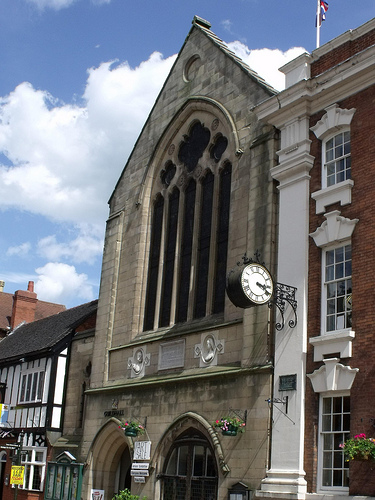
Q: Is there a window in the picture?
A: Yes, there are windows.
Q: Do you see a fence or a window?
A: Yes, there are windows.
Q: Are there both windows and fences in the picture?
A: No, there are windows but no fences.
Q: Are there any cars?
A: No, there are no cars.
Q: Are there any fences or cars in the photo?
A: No, there are no cars or fences.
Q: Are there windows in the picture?
A: Yes, there is a window.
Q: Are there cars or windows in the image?
A: Yes, there is a window.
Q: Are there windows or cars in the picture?
A: Yes, there is a window.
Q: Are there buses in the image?
A: No, there are no buses.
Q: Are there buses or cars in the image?
A: No, there are no buses or cars.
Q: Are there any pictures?
A: No, there are no pictures.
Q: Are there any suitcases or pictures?
A: No, there are no pictures or suitcases.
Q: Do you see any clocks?
A: Yes, there is a clock.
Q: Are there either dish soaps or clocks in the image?
A: Yes, there is a clock.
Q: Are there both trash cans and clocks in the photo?
A: No, there is a clock but no trash cans.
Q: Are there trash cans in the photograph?
A: No, there are no trash cans.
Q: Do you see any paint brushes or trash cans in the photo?
A: No, there are no trash cans or paint brushes.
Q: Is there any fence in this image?
A: No, there are no fences.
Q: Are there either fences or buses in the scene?
A: No, there are no fences or buses.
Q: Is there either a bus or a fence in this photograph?
A: No, there are no fences or buses.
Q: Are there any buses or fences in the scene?
A: No, there are no fences or buses.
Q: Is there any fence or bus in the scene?
A: No, there are no fences or buses.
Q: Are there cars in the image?
A: No, there are no cars.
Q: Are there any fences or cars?
A: No, there are no cars or fences.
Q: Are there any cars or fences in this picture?
A: No, there are no cars or fences.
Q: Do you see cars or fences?
A: No, there are no cars or fences.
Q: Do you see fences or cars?
A: No, there are no cars or fences.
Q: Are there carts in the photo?
A: No, there are no carts.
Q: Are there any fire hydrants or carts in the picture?
A: No, there are no carts or fire hydrants.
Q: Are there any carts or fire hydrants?
A: No, there are no carts or fire hydrants.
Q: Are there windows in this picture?
A: Yes, there are windows.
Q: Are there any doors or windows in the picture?
A: Yes, there are windows.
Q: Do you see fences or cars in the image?
A: No, there are no fences or cars.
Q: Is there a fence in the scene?
A: No, there are no fences.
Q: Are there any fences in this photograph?
A: No, there are no fences.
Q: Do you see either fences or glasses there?
A: No, there are no fences or glasses.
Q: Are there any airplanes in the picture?
A: No, there are no airplanes.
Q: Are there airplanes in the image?
A: No, there are no airplanes.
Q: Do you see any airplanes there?
A: No, there are no airplanes.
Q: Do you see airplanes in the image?
A: No, there are no airplanes.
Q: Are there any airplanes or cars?
A: No, there are no airplanes or cars.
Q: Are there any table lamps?
A: No, there are no table lamps.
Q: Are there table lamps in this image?
A: No, there are no table lamps.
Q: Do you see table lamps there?
A: No, there are no table lamps.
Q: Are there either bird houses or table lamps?
A: No, there are no table lamps or bird houses.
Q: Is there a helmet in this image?
A: No, there are no helmets.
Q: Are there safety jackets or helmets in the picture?
A: No, there are no helmets or safety jackets.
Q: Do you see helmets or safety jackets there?
A: No, there are no helmets or safety jackets.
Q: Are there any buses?
A: No, there are no buses.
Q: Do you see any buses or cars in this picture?
A: No, there are no buses or cars.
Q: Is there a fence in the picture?
A: No, there are no fences.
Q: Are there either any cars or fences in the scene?
A: No, there are no fences or cars.